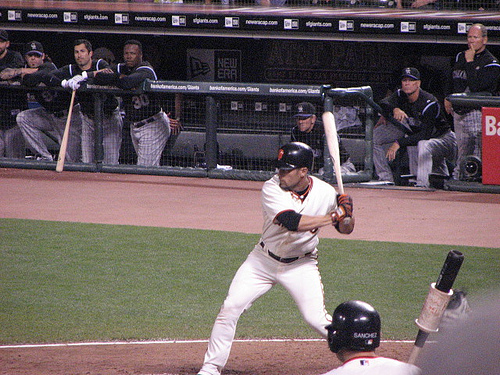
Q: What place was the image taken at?
A: It was taken at the field.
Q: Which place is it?
A: It is a field.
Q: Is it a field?
A: Yes, it is a field.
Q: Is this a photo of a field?
A: Yes, it is showing a field.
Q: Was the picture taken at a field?
A: Yes, it was taken in a field.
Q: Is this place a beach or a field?
A: It is a field.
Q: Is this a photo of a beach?
A: No, the picture is showing a field.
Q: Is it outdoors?
A: Yes, it is outdoors.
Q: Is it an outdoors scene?
A: Yes, it is outdoors.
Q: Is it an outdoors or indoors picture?
A: It is outdoors.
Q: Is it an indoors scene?
A: No, it is outdoors.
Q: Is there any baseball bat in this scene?
A: Yes, there is a baseball bat.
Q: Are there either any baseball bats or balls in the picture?
A: Yes, there is a baseball bat.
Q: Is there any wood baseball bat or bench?
A: Yes, there is a wood baseball bat.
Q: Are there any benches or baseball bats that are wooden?
A: Yes, the baseball bat is wooden.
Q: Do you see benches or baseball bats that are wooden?
A: Yes, the baseball bat is wooden.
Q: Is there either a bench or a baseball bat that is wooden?
A: Yes, the baseball bat is wooden.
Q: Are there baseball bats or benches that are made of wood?
A: Yes, the baseball bat is made of wood.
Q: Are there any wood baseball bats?
A: Yes, there is a wood baseball bat.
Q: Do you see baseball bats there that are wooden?
A: Yes, there is a baseball bat that is wooden.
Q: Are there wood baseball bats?
A: Yes, there is a baseball bat that is made of wood.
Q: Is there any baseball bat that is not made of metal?
A: Yes, there is a baseball bat that is made of wood.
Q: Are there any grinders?
A: No, there are no grinders.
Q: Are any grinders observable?
A: No, there are no grinders.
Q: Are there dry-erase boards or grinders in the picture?
A: No, there are no grinders or dry-erase boards.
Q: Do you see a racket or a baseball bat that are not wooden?
A: No, there is a baseball bat but it is wooden.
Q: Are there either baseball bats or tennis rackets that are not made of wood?
A: No, there is a baseball bat but it is made of wood.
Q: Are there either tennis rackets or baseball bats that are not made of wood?
A: No, there is a baseball bat but it is made of wood.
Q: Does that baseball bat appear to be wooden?
A: Yes, the baseball bat is wooden.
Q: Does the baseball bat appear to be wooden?
A: Yes, the baseball bat is wooden.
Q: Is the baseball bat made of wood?
A: Yes, the baseball bat is made of wood.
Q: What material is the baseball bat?
A: The baseball bat is made of wood.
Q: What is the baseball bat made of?
A: The baseball bat is made of wood.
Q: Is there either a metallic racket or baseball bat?
A: No, there is a baseball bat but it is wooden.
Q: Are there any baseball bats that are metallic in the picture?
A: No, there is a baseball bat but it is wooden.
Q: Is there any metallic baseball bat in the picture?
A: No, there is a baseball bat but it is wooden.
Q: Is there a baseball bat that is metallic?
A: No, there is a baseball bat but it is wooden.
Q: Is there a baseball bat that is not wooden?
A: No, there is a baseball bat but it is wooden.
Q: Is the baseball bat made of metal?
A: No, the baseball bat is made of wood.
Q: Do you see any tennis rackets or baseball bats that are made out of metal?
A: No, there is a baseball bat but it is made of wood.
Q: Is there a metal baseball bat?
A: No, there is a baseball bat but it is made of wood.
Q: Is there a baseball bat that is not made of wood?
A: No, there is a baseball bat but it is made of wood.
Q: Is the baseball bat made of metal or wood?
A: The baseball bat is made of wood.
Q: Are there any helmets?
A: Yes, there is a helmet.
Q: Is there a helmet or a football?
A: Yes, there is a helmet.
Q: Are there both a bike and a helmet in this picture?
A: No, there is a helmet but no bikes.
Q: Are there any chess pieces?
A: No, there are no chess pieces.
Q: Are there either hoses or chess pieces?
A: No, there are no chess pieces or hoses.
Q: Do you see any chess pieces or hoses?
A: No, there are no chess pieces or hoses.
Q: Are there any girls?
A: No, there are no girls.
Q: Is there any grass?
A: Yes, there is grass.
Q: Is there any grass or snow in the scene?
A: Yes, there is grass.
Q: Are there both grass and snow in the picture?
A: No, there is grass but no snow.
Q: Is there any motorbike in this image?
A: No, there are no motorcycles.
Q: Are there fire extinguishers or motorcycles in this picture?
A: No, there are no motorcycles or fire extinguishers.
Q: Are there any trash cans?
A: No, there are no trash cans.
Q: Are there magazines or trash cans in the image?
A: No, there are no trash cans or magazines.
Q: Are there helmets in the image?
A: Yes, there is a helmet.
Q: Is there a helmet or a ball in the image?
A: Yes, there is a helmet.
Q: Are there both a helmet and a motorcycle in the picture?
A: No, there is a helmet but no motorcycles.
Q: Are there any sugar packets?
A: No, there are no sugar packets.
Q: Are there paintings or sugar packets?
A: No, there are no sugar packets or paintings.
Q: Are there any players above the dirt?
A: Yes, there is a player above the dirt.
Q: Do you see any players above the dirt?
A: Yes, there is a player above the dirt.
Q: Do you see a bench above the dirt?
A: No, there is a player above the dirt.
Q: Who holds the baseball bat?
A: The player holds the baseball bat.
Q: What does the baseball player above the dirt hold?
A: The player holds the baseball bat.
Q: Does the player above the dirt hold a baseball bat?
A: Yes, the player holds a baseball bat.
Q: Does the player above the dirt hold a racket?
A: No, the player holds a baseball bat.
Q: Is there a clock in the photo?
A: No, there are no clocks.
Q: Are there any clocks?
A: No, there are no clocks.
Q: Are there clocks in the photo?
A: No, there are no clocks.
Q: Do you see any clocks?
A: No, there are no clocks.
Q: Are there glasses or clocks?
A: No, there are no clocks or glasses.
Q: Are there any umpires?
A: No, there are no umpires.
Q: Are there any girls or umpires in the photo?
A: No, there are no umpires or girls.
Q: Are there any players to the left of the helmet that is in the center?
A: Yes, there is a player to the left of the helmet.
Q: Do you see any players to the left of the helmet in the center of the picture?
A: Yes, there is a player to the left of the helmet.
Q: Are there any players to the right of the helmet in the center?
A: No, the player is to the left of the helmet.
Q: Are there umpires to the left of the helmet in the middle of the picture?
A: No, there is a player to the left of the helmet.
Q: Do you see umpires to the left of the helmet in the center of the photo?
A: No, there is a player to the left of the helmet.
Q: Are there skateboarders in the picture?
A: No, there are no skateboarders.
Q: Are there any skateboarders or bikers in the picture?
A: No, there are no skateboarders or bikers.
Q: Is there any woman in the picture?
A: No, there are no women.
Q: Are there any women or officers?
A: No, there are no women or officers.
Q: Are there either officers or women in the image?
A: No, there are no women or officers.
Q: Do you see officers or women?
A: No, there are no women or officers.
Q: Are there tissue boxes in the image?
A: No, there are no tissue boxes.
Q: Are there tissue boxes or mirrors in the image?
A: No, there are no tissue boxes or mirrors.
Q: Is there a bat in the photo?
A: Yes, there is a bat.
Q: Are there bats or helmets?
A: Yes, there is a bat.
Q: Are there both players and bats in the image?
A: Yes, there are both a bat and a player.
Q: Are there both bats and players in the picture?
A: Yes, there are both a bat and a player.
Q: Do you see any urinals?
A: No, there are no urinals.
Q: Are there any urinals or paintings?
A: No, there are no urinals or paintings.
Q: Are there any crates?
A: No, there are no crates.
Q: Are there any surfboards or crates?
A: No, there are no crates or surfboards.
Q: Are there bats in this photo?
A: Yes, there is a bat.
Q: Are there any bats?
A: Yes, there is a bat.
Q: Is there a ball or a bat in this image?
A: Yes, there is a bat.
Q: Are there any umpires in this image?
A: No, there are no umpires.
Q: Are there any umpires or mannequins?
A: No, there are no umpires or mannequins.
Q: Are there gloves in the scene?
A: Yes, there are gloves.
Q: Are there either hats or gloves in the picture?
A: Yes, there are gloves.